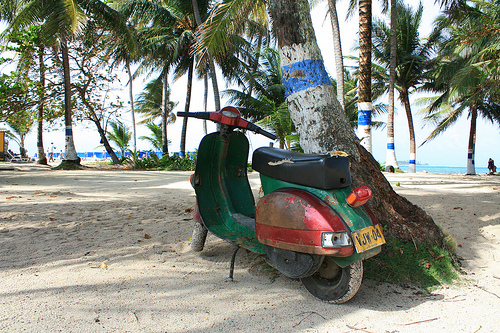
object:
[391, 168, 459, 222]
ground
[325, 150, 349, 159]
tear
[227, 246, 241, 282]
center stand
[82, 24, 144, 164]
tree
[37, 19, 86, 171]
tree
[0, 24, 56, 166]
tree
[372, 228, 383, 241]
number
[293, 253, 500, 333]
twigs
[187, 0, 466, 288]
tree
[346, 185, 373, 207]
light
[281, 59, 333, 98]
blue stripe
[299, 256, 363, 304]
tire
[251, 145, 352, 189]
seat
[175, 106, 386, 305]
bike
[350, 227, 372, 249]
plate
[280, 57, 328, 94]
paint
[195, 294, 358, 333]
shade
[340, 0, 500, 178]
trees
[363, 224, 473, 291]
grass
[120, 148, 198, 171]
shrub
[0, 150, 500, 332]
beach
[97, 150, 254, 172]
grass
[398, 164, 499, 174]
water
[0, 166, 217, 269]
shade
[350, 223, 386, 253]
liscense plate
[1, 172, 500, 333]
sand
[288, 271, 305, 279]
edge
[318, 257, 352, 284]
exhaust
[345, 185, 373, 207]
tail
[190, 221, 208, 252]
tire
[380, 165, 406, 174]
grass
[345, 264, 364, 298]
dirt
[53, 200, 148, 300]
sand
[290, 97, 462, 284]
tree trunk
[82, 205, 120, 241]
part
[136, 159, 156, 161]
part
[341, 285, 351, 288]
part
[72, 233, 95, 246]
part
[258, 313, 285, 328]
part